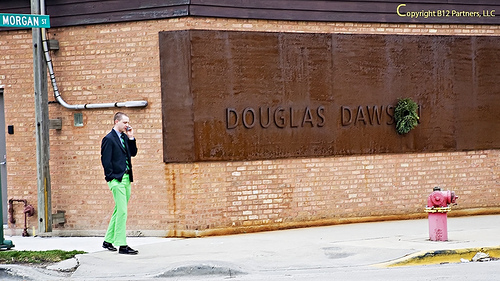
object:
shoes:
[117, 244, 142, 254]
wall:
[161, 30, 498, 227]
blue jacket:
[98, 126, 138, 182]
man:
[91, 104, 142, 258]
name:
[224, 104, 398, 126]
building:
[4, 3, 499, 235]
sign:
[0, 12, 50, 29]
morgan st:
[2, 14, 47, 24]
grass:
[6, 242, 44, 260]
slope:
[163, 253, 236, 279]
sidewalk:
[204, 192, 401, 277]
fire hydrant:
[423, 186, 460, 243]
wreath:
[391, 97, 422, 135]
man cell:
[113, 111, 134, 138]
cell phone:
[125, 127, 131, 131]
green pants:
[104, 171, 134, 245]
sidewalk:
[45, 225, 172, 279]